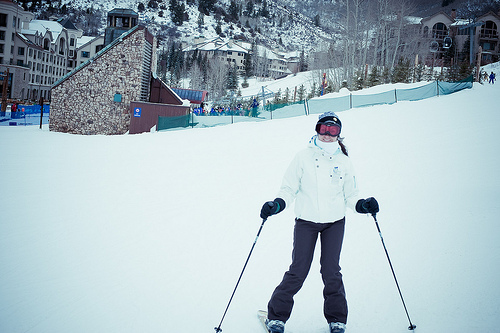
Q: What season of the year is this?
A: Winter.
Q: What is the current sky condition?
A: Cloudy.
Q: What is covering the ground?
A: Snow.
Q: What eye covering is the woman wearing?
A: Ski goggles.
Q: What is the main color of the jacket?
A: White.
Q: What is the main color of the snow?
A: White.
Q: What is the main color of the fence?
A: Green.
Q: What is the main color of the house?
A: Brown.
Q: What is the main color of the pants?
A: Black.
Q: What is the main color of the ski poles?
A: Black.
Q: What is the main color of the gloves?
A: Black.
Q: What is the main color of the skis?
A: White.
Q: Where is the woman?
A: On the snow.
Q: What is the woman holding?
A: Ski poles.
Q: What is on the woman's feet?
A: Skis.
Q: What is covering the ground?
A: Snow.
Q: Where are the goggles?
A: On the woman's face.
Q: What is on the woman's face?
A: A pair of goggles.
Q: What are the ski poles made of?
A: Metal.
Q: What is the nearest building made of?
A: Stone.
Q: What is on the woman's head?
A: A hat.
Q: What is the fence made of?
A: Green fabric.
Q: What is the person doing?
A: Skiing.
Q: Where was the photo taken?
A: Ski resort.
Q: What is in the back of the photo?
A: Housing.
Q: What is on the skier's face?
A: Goggles.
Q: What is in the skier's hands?
A: Poles.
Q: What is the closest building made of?
A: Brick.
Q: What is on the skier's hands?
A: Gloves.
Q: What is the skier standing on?
A: Skis.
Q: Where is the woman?
A: At a ski resort.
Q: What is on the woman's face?
A: Goggles.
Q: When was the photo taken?
A: Daytime.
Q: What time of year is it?
A: Winter.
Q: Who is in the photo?
A: A woman.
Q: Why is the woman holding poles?
A: She's skiing.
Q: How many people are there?
A: One.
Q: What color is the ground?
A: White.